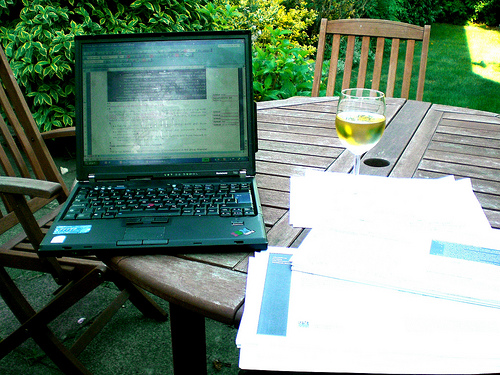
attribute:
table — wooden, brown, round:
[99, 93, 496, 371]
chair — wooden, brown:
[311, 17, 430, 100]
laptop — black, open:
[38, 32, 267, 253]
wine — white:
[337, 113, 385, 151]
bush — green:
[1, 0, 316, 132]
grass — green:
[325, 25, 500, 112]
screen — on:
[81, 39, 248, 165]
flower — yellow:
[276, 10, 283, 20]